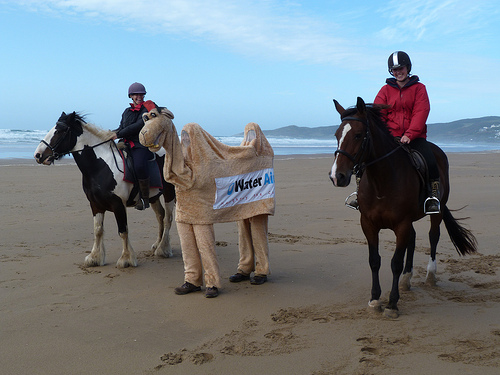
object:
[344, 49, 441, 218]
person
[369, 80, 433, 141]
jacket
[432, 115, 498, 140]
hill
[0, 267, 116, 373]
sand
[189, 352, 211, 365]
footprint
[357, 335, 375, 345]
footprint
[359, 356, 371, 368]
footprint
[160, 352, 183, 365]
footprint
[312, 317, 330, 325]
footprint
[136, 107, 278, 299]
camel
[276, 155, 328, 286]
ground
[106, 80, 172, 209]
person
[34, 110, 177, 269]
horse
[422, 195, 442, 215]
stirrup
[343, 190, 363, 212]
stirrup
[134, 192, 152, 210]
stirrup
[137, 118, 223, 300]
people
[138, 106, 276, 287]
costume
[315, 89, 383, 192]
head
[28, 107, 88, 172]
head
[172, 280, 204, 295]
shoe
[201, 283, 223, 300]
shoe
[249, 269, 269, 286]
shoe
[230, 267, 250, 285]
shoe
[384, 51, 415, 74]
helmet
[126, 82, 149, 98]
helmet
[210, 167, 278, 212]
advertisement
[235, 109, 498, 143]
foot hill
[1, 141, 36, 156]
water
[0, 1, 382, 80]
sky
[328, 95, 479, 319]
horse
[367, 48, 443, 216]
rider